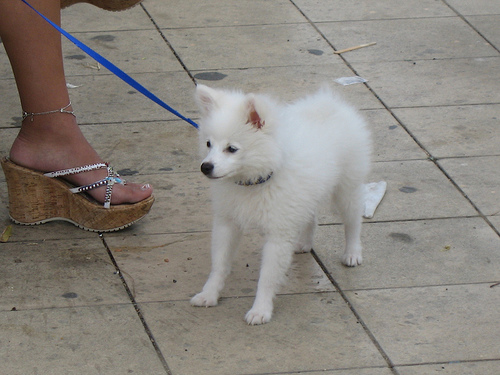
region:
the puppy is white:
[172, 64, 386, 311]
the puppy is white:
[158, 68, 393, 322]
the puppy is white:
[164, 71, 402, 356]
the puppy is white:
[170, 65, 400, 349]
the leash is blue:
[45, 21, 227, 188]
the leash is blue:
[73, 37, 187, 150]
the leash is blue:
[64, 28, 187, 140]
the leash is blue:
[62, 21, 184, 139]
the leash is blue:
[82, 52, 190, 141]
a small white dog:
[189, 83, 370, 325]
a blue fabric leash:
[23, 1, 198, 128]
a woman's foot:
[0, 0, 152, 206]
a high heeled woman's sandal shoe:
[3, 152, 156, 232]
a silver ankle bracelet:
[18, 103, 77, 120]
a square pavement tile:
[0, 303, 167, 374]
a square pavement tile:
[134, 289, 392, 374]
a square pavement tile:
[341, 279, 499, 364]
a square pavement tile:
[308, 215, 499, 289]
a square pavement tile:
[103, 233, 338, 300]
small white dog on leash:
[147, 62, 387, 342]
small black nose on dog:
[195, 160, 216, 178]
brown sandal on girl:
[2, 164, 156, 234]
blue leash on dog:
[41, 27, 225, 138]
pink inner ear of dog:
[238, 95, 261, 132]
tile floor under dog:
[108, 31, 498, 316]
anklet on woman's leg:
[14, 93, 85, 138]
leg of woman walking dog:
[0, 12, 128, 229]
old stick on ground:
[327, 27, 384, 64]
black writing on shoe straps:
[97, 175, 121, 212]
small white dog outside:
[192, 77, 384, 318]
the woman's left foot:
[12, 120, 151, 201]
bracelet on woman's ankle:
[20, 102, 73, 119]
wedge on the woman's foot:
[4, 166, 161, 230]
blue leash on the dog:
[62, 24, 199, 133]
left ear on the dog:
[245, 94, 263, 132]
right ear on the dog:
[188, 82, 220, 112]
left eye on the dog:
[225, 143, 239, 157]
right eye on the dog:
[199, 139, 215, 150]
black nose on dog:
[199, 160, 213, 179]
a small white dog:
[169, 74, 395, 334]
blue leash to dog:
[28, 5, 275, 202]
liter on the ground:
[316, 32, 421, 233]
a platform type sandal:
[5, 155, 176, 247]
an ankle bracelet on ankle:
[16, 91, 93, 128]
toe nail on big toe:
[136, 181, 151, 197]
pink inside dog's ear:
[248, 109, 261, 131]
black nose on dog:
[198, 160, 219, 184]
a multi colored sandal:
[27, 147, 166, 214]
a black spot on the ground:
[178, 57, 230, 86]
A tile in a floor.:
[102, 222, 337, 295]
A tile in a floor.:
[133, 289, 390, 374]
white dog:
[163, 80, 389, 329]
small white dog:
[153, 80, 385, 320]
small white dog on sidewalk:
[186, 68, 374, 329]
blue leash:
[87, 49, 176, 113]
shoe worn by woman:
[15, 147, 152, 254]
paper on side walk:
[333, 63, 370, 93]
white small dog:
[162, 69, 387, 335]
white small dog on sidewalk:
[168, 67, 388, 331]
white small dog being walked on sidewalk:
[178, 75, 379, 323]